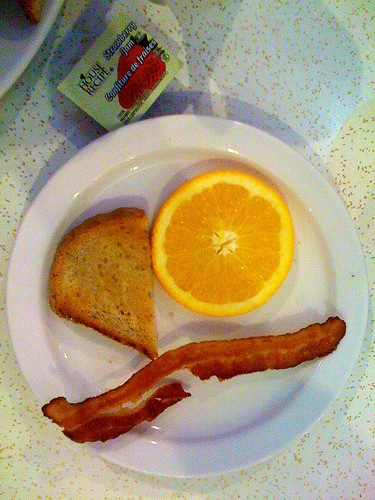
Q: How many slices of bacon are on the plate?
A: One.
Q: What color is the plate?
A: White.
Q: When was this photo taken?
A: Breakfast time.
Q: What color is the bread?
A: Brown.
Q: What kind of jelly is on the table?
A: Strawberry.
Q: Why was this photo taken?
A: To show what breakfast looks like.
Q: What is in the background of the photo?
A: More food on another plate.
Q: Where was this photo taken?
A: At breakfast.